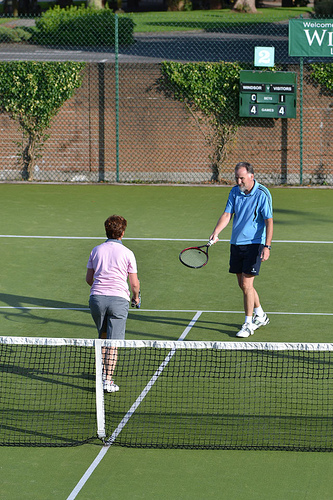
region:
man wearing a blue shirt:
[153, 149, 330, 350]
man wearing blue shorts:
[171, 154, 265, 342]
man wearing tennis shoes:
[168, 146, 265, 340]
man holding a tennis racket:
[165, 152, 309, 339]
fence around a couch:
[129, 108, 201, 182]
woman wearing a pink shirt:
[89, 187, 144, 341]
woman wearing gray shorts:
[98, 209, 129, 340]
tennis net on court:
[105, 333, 323, 457]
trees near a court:
[21, 51, 70, 181]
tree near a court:
[169, 59, 229, 162]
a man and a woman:
[61, 163, 291, 391]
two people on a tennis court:
[67, 161, 293, 395]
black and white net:
[0, 331, 332, 454]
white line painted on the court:
[62, 444, 111, 498]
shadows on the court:
[2, 285, 90, 332]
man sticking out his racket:
[173, 156, 294, 338]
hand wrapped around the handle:
[205, 228, 223, 244]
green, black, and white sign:
[235, 70, 306, 124]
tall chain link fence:
[2, 12, 332, 188]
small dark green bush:
[36, 7, 138, 46]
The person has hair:
[100, 211, 170, 257]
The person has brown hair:
[102, 209, 133, 242]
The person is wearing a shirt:
[74, 235, 150, 298]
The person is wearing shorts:
[79, 285, 140, 352]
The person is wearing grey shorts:
[76, 289, 140, 350]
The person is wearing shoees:
[92, 369, 127, 395]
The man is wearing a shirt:
[214, 177, 280, 243]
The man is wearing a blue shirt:
[219, 181, 279, 244]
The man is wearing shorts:
[217, 236, 271, 287]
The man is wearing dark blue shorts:
[223, 239, 278, 287]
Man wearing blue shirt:
[184, 147, 283, 351]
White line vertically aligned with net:
[78, 333, 118, 447]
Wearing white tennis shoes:
[225, 314, 273, 334]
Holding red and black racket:
[176, 237, 216, 277]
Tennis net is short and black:
[3, 341, 331, 448]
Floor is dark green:
[4, 186, 327, 450]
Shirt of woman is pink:
[83, 232, 138, 295]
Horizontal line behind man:
[3, 301, 331, 321]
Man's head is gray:
[228, 151, 260, 202]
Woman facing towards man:
[65, 222, 168, 381]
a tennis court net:
[0, 337, 329, 451]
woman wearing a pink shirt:
[88, 240, 137, 303]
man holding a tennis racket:
[178, 237, 218, 267]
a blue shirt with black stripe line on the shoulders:
[225, 180, 273, 244]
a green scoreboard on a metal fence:
[239, 68, 299, 119]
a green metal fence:
[0, 12, 332, 185]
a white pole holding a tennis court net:
[93, 341, 106, 440]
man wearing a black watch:
[262, 242, 271, 251]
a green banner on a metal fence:
[289, 19, 331, 59]